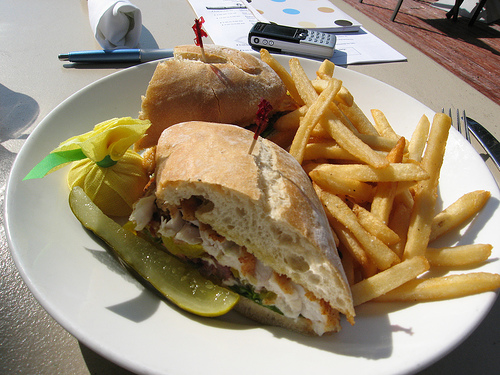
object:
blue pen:
[57, 48, 142, 63]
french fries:
[269, 56, 497, 307]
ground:
[410, 23, 497, 101]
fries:
[308, 123, 478, 278]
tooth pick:
[247, 100, 273, 154]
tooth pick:
[192, 16, 207, 62]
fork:
[442, 108, 472, 146]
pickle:
[67, 185, 240, 319]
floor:
[454, 31, 500, 71]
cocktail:
[68, 185, 236, 317]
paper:
[344, 32, 408, 72]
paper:
[332, 30, 382, 67]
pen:
[57, 47, 187, 67]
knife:
[460, 115, 500, 173]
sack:
[21, 116, 151, 216]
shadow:
[104, 286, 163, 323]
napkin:
[85, 0, 142, 50]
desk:
[0, 0, 499, 373]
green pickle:
[68, 184, 241, 318]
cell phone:
[247, 21, 337, 60]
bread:
[155, 120, 355, 327]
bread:
[133, 45, 286, 153]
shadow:
[262, 309, 392, 364]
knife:
[459, 111, 500, 169]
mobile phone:
[247, 21, 335, 60]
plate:
[3, 51, 499, 375]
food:
[68, 46, 500, 336]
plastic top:
[192, 16, 209, 61]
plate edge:
[2, 216, 157, 373]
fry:
[345, 254, 428, 306]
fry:
[285, 51, 385, 170]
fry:
[288, 74, 343, 164]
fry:
[427, 238, 491, 268]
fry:
[403, 107, 455, 211]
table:
[1, 0, 499, 372]